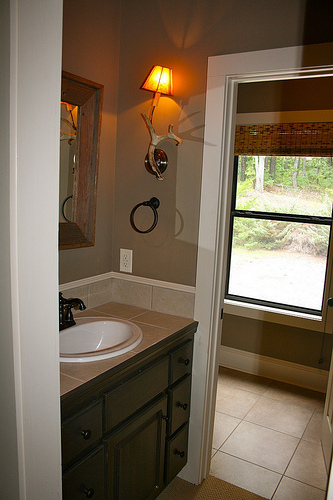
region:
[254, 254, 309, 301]
part of a ventilation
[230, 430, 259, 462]
part of a floor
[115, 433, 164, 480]
part of a cupboard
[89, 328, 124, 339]
inner part of a sink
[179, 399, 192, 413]
part of a handle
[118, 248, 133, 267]
part of a switch on a wall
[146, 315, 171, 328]
surface of the sink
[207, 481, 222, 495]
part of a carpet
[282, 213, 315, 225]
part of a black boundary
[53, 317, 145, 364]
white porcelain sink basin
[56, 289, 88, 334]
black metal sink faucet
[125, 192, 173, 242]
black towel hoop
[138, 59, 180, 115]
orange illuminated lamp shade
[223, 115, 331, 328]
window with black trim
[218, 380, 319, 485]
tan tile floor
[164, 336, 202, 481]
three dark wooden drawers with knobs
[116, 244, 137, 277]
plastic white wall outlet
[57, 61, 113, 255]
half a mirror with a wooden frame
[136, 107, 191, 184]
tan antler hanging on a wall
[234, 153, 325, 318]
A window.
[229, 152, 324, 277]
A forest is outside.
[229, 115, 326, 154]
The window's blinds are up.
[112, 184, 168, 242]
A metal object to hang towels on.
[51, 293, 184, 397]
The counter is made from tile.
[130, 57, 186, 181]
The light fixture is partially made from antler.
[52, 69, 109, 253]
A framed mirror.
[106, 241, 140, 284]
An electrical outlet.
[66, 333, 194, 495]
Drawers and cabinets made from dark colored wood.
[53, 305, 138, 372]
The sink is white.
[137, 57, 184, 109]
the light is on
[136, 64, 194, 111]
the light is yellow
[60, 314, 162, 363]
the sink is white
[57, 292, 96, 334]
the faucet is black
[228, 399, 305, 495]
the floor is tiled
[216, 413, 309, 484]
the tiles are square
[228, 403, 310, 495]
the floor is beige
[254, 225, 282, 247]
the grass is green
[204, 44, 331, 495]
the door is open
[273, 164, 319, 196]
the leaves are green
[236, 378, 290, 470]
the floor is tiled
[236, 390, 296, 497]
the floor is white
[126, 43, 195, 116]
the light is on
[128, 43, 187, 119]
the light is orange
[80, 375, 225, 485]
the cabinets are brown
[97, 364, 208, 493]
the cabinets are wooden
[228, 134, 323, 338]
the window is closed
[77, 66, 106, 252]
the frame is brown